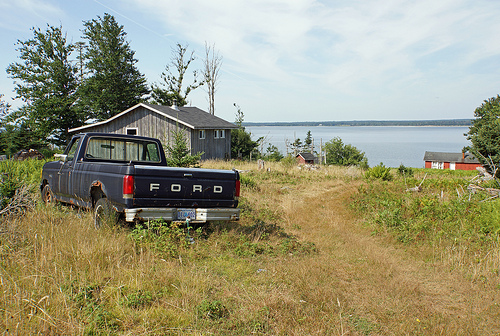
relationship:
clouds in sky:
[225, 28, 343, 105] [4, 0, 498, 119]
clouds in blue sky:
[140, 0, 500, 123] [133, 16, 398, 96]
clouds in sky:
[227, 22, 480, 109] [4, 0, 498, 119]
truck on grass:
[34, 130, 246, 234] [2, 215, 329, 332]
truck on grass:
[34, 130, 246, 234] [343, 177, 498, 264]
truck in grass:
[41, 130, 242, 234] [323, 187, 350, 224]